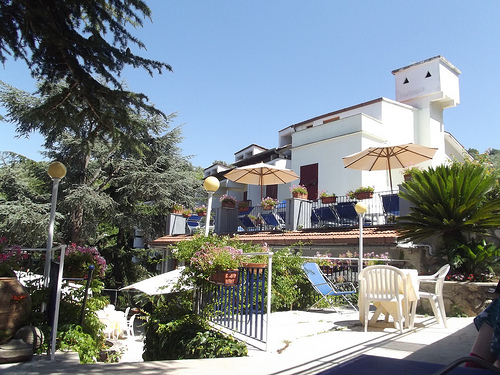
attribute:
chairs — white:
[352, 268, 449, 340]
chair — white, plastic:
[359, 265, 403, 318]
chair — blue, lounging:
[298, 248, 360, 308]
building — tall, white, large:
[266, 43, 454, 206]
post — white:
[356, 218, 366, 290]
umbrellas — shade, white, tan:
[225, 156, 405, 171]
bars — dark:
[200, 271, 265, 335]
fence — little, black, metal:
[192, 261, 264, 339]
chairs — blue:
[216, 198, 294, 241]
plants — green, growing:
[187, 218, 310, 321]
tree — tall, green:
[25, 8, 150, 131]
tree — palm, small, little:
[399, 167, 499, 264]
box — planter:
[209, 267, 267, 293]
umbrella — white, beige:
[325, 127, 439, 184]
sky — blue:
[142, 11, 490, 141]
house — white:
[212, 64, 460, 223]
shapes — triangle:
[401, 71, 435, 88]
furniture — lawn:
[298, 243, 461, 336]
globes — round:
[355, 194, 376, 213]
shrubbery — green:
[178, 236, 317, 300]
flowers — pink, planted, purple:
[193, 232, 239, 262]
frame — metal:
[300, 248, 355, 299]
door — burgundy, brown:
[300, 165, 319, 210]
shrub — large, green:
[147, 291, 210, 349]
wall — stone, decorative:
[407, 283, 485, 312]